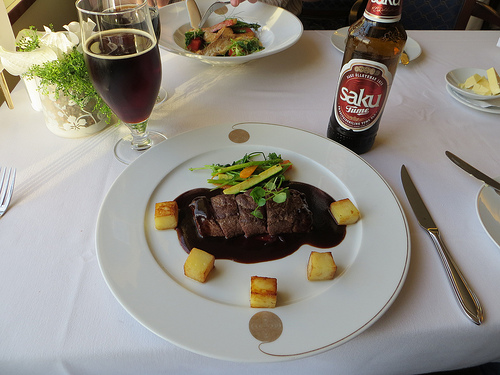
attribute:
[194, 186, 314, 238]
steak — well done, large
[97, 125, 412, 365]
plate — white, gold, large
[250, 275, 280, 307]
pineapple cut — square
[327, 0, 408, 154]
saku beer bottle — big, brown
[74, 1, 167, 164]
wine glass — full, medium sized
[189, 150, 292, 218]
garnish — a small section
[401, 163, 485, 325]
knife — small, long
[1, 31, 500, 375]
table — pure white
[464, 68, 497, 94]
butter — yellow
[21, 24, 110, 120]
plant — green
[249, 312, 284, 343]
art — brown, circular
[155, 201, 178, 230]
cubed potato — tiny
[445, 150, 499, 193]
butter knife — silver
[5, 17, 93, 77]
table decoration — white, frilly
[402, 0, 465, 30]
chair back — black, yellow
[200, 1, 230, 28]
dining fork — small